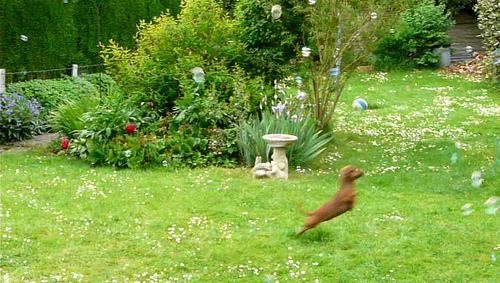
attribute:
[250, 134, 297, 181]
bird bath —  concrete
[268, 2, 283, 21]
bubble — clear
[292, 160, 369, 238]
puppy — brown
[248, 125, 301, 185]
birdbath —  tan in colored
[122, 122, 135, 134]
blossom — large, red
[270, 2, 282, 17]
bubble — clear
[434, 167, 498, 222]
bubbles — soap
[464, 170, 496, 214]
flowers —  white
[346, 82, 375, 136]
ball — blue, white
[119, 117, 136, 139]
flower —  red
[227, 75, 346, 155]
flowers — iris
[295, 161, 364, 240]
dog — brown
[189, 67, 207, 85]
bubble — clear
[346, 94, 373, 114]
bubble — clear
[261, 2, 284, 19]
bubble — clear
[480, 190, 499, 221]
bubble — clear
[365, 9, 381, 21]
bubble — clear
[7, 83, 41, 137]
flowers — purple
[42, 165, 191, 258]
flowers — white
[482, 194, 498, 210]
bubble — clear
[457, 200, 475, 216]
bubble — clear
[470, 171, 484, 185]
bubble — clear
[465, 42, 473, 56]
bubble — clear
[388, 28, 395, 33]
bubble — clear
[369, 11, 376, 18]
bubble — clear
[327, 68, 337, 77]
bubble — clear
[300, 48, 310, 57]
bubble — clear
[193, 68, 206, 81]
bubble — clear